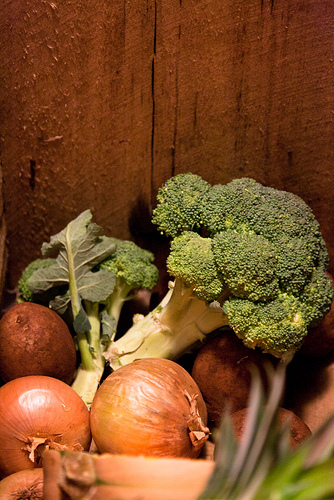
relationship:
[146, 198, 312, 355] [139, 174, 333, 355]
piece of broccoli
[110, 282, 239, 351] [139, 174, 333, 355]
stalk of broccoli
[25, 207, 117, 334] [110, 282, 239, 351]
leaf on stalk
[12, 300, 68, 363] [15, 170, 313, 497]
potato on vegetables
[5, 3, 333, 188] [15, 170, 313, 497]
box holding vegetables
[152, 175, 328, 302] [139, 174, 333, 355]
head of broccoli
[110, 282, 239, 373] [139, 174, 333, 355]
stalk of broccoli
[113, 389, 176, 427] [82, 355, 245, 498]
skin of onion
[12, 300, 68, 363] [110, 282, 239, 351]
potato under stalk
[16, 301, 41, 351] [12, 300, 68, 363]
skin of potato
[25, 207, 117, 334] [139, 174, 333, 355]
leaf of broccoli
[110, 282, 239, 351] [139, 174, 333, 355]
stalk on broccoli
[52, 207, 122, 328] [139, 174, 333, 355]
leaf on broccoli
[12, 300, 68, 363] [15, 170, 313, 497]
potato with vegetables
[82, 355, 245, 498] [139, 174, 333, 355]
onion in front of broccoli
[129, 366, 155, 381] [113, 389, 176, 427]
water on skin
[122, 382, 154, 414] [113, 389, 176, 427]
reflection on skin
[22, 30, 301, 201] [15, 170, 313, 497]
plant behind vegetables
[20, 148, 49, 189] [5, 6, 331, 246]
oval in plank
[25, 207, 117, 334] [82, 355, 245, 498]
leaf next to onion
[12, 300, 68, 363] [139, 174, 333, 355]
potato under broccoli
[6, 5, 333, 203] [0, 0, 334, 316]
wall of box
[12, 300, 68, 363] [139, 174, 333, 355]
potato by broccoli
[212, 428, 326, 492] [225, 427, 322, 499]
leaves of scallion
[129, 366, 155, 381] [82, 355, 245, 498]
water on onion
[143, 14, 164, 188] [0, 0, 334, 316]
crack on box